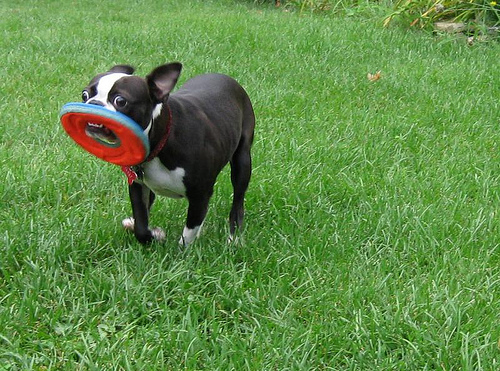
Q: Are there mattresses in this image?
A: No, there are no mattresses.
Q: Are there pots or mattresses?
A: No, there are no mattresses or pots.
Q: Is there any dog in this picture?
A: Yes, there is a dog.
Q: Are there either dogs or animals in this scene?
A: Yes, there is a dog.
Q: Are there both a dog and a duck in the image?
A: No, there is a dog but no ducks.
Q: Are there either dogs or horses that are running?
A: Yes, the dog is running.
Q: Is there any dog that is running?
A: Yes, there is a dog that is running.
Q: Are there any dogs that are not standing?
A: Yes, there is a dog that is running.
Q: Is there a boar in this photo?
A: No, there are no boars.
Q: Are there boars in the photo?
A: No, there are no boars.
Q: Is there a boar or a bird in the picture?
A: No, there are no boars or birds.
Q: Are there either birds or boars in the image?
A: No, there are no boars or birds.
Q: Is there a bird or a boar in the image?
A: No, there are no boars or birds.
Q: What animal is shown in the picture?
A: The animal is a dog.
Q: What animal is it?
A: The animal is a dog.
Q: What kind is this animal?
A: That is a dog.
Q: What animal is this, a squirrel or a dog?
A: That is a dog.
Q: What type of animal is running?
A: The animal is a dog.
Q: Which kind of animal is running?
A: The animal is a dog.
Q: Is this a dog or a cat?
A: This is a dog.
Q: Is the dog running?
A: Yes, the dog is running.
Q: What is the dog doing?
A: The dog is running.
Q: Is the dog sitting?
A: No, the dog is running.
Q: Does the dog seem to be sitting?
A: No, the dog is running.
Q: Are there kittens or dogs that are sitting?
A: No, there is a dog but it is running.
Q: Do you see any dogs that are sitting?
A: No, there is a dog but it is running.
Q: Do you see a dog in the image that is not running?
A: No, there is a dog but it is running.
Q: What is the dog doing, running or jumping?
A: The dog is running.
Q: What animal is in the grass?
A: The animal is a dog.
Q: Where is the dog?
A: The dog is in the grass.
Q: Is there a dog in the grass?
A: Yes, there is a dog in the grass.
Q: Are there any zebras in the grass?
A: No, there is a dog in the grass.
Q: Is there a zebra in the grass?
A: No, there is a dog in the grass.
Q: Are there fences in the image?
A: No, there are no fences.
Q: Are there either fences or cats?
A: No, there are no fences or cats.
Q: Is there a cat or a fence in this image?
A: No, there are no fences or cats.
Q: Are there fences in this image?
A: No, there are no fences.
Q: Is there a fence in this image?
A: No, there are no fences.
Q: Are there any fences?
A: No, there are no fences.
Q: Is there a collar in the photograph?
A: Yes, there is a collar.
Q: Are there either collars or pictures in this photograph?
A: Yes, there is a collar.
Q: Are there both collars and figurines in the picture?
A: No, there is a collar but no figurines.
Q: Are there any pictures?
A: No, there are no pictures.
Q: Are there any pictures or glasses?
A: No, there are no pictures or glasses.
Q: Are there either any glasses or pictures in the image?
A: No, there are no pictures or glasses.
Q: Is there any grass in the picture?
A: Yes, there is grass.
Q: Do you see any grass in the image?
A: Yes, there is grass.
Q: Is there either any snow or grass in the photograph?
A: Yes, there is grass.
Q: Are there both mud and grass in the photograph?
A: No, there is grass but no mud.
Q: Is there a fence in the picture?
A: No, there are no fences.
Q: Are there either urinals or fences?
A: No, there are no fences or urinals.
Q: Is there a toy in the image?
A: Yes, there is a toy.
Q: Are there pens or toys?
A: Yes, there is a toy.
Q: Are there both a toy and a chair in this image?
A: No, there is a toy but no chairs.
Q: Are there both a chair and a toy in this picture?
A: No, there is a toy but no chairs.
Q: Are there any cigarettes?
A: No, there are no cigarettes.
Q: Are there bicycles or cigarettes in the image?
A: No, there are no cigarettes or bicycles.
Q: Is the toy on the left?
A: Yes, the toy is on the left of the image.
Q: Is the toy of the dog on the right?
A: No, the toy is on the left of the image.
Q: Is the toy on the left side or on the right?
A: The toy is on the left of the image.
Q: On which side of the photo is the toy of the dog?
A: The toy is on the left of the image.